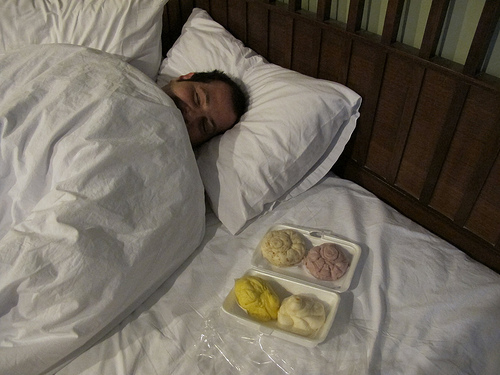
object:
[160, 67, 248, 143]
head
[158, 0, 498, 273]
headboard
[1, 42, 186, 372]
white comforter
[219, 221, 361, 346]
container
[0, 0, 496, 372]
bed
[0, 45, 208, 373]
comforter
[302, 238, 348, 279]
food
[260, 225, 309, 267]
food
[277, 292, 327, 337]
food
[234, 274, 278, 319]
food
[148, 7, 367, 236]
pillow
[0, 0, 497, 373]
bedrooom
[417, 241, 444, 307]
sheet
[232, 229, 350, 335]
pastry